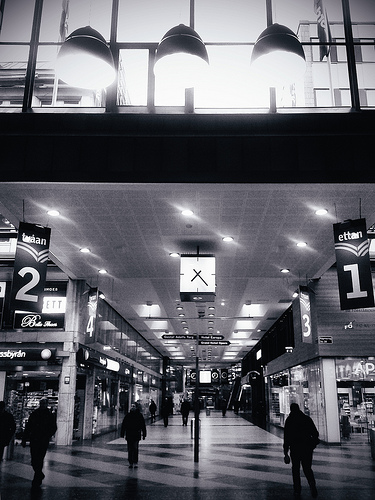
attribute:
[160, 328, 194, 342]
sign — black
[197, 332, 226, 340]
sign — black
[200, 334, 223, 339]
lettering — white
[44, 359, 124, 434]
doorway — in the picture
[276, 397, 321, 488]
person — in the picture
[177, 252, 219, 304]
square clock — white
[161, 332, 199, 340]
sign — black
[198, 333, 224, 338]
sign — black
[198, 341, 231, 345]
sign — black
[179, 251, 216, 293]
clock — in the picture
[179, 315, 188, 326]
light — overhead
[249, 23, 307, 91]
light fixture — hanging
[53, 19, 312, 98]
fixture — hanging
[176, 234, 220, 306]
clock — in the picture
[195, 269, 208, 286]
hand — long, black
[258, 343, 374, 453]
store — in the picture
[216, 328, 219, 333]
light — overhead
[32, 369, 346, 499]
people — in the picture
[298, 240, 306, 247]
light — overhead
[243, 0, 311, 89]
light — in the picture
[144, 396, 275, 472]
floor — striped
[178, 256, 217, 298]
clock — large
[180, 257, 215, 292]
clock face — white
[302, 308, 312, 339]
number — hanging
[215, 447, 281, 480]
tile — black, white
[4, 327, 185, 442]
storefronts — in the picture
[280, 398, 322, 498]
person — walking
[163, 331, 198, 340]
writing — white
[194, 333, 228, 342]
writing — white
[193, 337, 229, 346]
writing — white